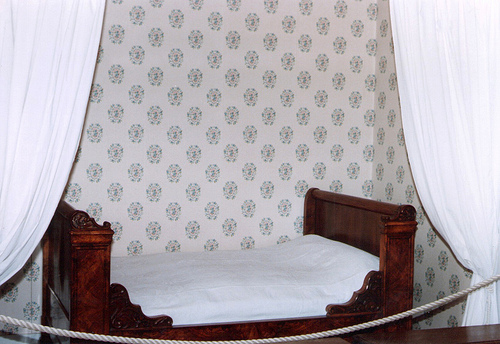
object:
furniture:
[36, 186, 417, 343]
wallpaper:
[0, 0, 500, 344]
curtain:
[387, 0, 500, 329]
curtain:
[0, 0, 107, 290]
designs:
[114, 34, 336, 179]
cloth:
[0, 0, 112, 287]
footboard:
[40, 198, 110, 336]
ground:
[367, 140, 443, 175]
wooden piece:
[326, 267, 379, 314]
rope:
[1, 279, 499, 343]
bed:
[41, 188, 416, 343]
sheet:
[108, 234, 380, 327]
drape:
[392, 0, 499, 328]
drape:
[0, 0, 103, 288]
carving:
[326, 269, 383, 318]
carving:
[110, 282, 173, 331]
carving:
[69, 210, 99, 231]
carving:
[381, 203, 417, 221]